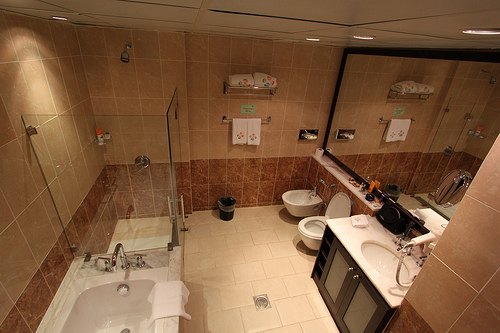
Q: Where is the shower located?
A: In the bathroom.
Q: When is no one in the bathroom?
A: Now.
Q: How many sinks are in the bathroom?
A: One.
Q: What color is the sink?
A: White.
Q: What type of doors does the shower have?
A: Glass doors.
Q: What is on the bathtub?
A: A towel.